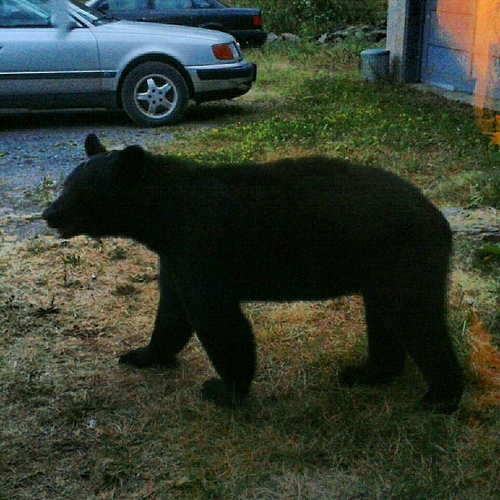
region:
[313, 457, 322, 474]
part of a field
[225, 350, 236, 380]
back of a leg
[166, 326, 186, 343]
front leg of a bear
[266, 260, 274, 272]
side of a bear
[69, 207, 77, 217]
mouth of a bear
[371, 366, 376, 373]
back leg of a bear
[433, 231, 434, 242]
back of a bear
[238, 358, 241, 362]
back of a leg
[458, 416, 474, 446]
part of the grass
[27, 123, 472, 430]
black bear walking across lawn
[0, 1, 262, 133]
silver car parked on gravel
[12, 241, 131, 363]
patches of green and yellow grass on lawn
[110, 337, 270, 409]
two front bear paws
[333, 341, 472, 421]
two black bear hind paws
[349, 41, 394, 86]
raised conical shaped structure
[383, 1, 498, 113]
egde of grey garage door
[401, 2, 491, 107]
dark shadow on garage door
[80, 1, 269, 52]
parked black four door car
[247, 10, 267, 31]
rear drivers side light of black four door car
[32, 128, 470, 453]
black bear on ground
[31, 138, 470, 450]
big black bear on ground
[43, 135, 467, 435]
heavy black bear on ground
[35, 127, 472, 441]
strong black bear on ground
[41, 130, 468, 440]
wild black bear on ground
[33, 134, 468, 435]
hungry black bear on ground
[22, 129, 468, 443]
large black bear on ground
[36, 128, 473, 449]
big strong black bear on ground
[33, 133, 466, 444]
big dark bear on ground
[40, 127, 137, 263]
head of a bear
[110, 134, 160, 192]
ear of the bear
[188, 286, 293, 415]
leg of the bear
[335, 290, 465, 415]
back legs of the bear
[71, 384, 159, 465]
ground next to the bear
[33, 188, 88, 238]
nose of the bear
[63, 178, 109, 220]
eye of the bear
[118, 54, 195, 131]
tire on the ground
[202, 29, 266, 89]
lights on front of car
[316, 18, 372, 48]
rocks in the background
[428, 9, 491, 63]
light hitting the wall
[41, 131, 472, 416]
Bear is standing on the ground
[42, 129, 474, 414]
Black bear is standing on the ground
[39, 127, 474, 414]
Bear is standing on the grass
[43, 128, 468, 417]
Black bear is standing on the grass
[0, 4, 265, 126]
Car is parked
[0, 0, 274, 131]
Cars are parked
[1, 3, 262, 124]
Silver car is parked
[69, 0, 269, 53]
Black car is parked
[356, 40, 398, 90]
Trash can on the grass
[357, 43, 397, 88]
Trash can next to building